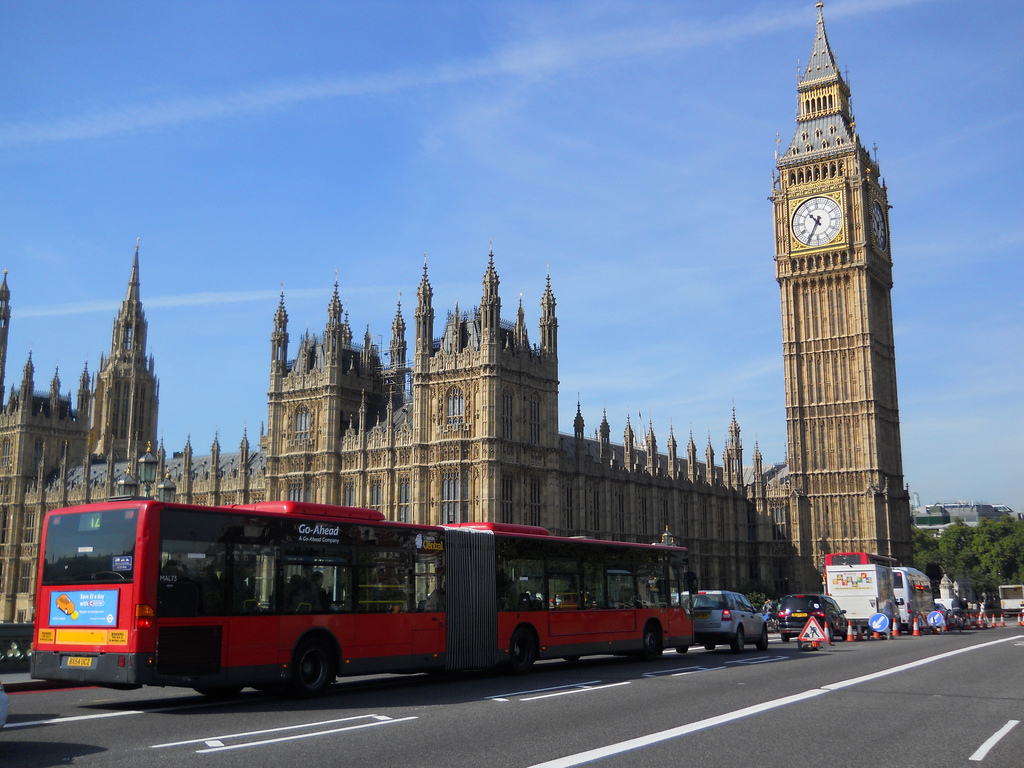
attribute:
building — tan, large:
[1, 10, 922, 611]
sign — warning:
[791, 607, 833, 646]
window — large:
[153, 512, 682, 646]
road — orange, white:
[7, 609, 1013, 766]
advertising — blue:
[39, 582, 131, 631]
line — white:
[546, 629, 1019, 766]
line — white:
[951, 707, 1016, 766]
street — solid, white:
[3, 614, 1019, 764]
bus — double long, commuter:
[31, 494, 692, 706]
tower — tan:
[771, 0, 914, 566]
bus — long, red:
[32, 486, 687, 687]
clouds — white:
[204, 65, 637, 243]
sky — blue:
[234, 124, 374, 213]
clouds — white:
[6, 3, 1016, 500]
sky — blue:
[3, 1, 1022, 517]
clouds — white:
[116, 65, 616, 202]